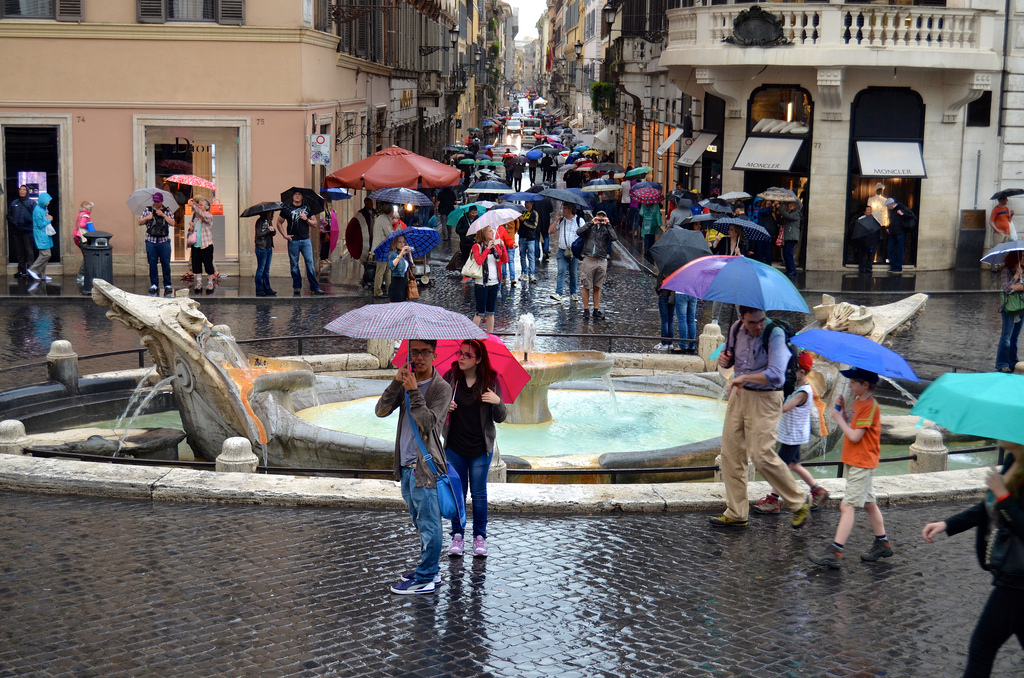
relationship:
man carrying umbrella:
[711, 301, 817, 541] [650, 245, 815, 328]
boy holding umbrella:
[810, 365, 904, 580] [776, 324, 932, 396]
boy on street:
[374, 334, 451, 601] [0, 465, 1022, 671]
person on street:
[443, 335, 507, 560] [0, 465, 1022, 671]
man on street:
[710, 301, 816, 541] [0, 465, 1022, 671]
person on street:
[784, 353, 843, 526] [0, 465, 1022, 671]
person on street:
[924, 430, 1022, 672] [0, 465, 1022, 671]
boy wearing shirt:
[810, 365, 905, 580] [834, 368, 887, 475]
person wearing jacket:
[30, 178, 65, 295] [30, 180, 59, 261]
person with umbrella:
[442, 335, 505, 573] [384, 325, 532, 401]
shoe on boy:
[383, 571, 438, 595] [360, 361, 462, 595]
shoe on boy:
[383, 571, 438, 595] [369, 361, 463, 614]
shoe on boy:
[380, 552, 445, 604] [349, 363, 440, 616]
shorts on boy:
[840, 461, 880, 513] [352, 353, 489, 595]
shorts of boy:
[840, 461, 892, 516] [818, 389, 914, 599]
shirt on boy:
[833, 394, 883, 470] [807, 363, 920, 571]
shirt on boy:
[841, 394, 884, 470] [831, 383, 901, 574]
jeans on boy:
[394, 456, 448, 579] [374, 334, 451, 601]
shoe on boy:
[383, 571, 438, 595] [371, 335, 465, 621]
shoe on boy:
[383, 571, 438, 595] [352, 314, 463, 634]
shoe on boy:
[383, 571, 438, 595] [362, 322, 490, 631]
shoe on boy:
[383, 571, 438, 595] [371, 336, 449, 637]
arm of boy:
[397, 368, 475, 429] [356, 357, 486, 639]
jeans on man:
[394, 456, 448, 579] [386, 461, 473, 555]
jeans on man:
[391, 456, 452, 578] [362, 320, 492, 602]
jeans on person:
[395, 463, 462, 576] [443, 335, 507, 560]